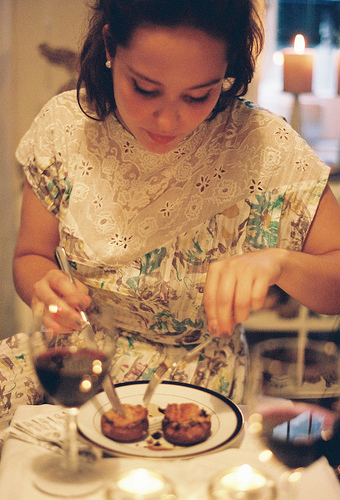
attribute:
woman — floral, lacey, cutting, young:
[6, 15, 338, 391]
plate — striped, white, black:
[56, 351, 286, 453]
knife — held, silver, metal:
[93, 382, 133, 412]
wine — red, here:
[35, 342, 112, 389]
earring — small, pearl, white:
[103, 50, 129, 80]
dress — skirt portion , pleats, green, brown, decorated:
[12, 94, 322, 390]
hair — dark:
[92, 10, 285, 64]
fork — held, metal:
[130, 359, 188, 415]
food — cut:
[100, 393, 216, 443]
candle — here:
[273, 39, 332, 95]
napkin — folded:
[14, 400, 79, 441]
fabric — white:
[57, 111, 242, 256]